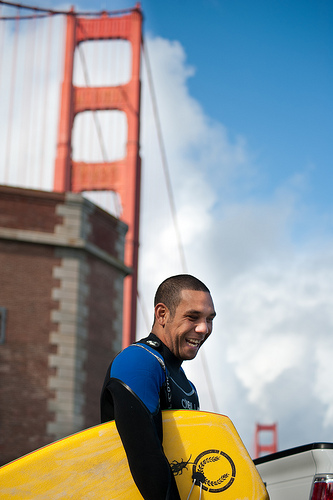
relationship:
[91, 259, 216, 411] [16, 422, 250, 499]
man carrying surfboard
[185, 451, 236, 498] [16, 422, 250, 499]
logo on surfboard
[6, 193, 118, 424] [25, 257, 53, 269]
wall made of brick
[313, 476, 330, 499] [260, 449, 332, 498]
tail light of truck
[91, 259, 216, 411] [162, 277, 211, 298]
man has hair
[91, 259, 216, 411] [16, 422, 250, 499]
man holding surfboard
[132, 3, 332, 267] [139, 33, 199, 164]
sky has cloud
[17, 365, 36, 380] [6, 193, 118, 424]
brick in wall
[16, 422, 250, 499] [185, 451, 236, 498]
surfboard has logo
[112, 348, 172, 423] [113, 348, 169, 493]
wetsuit has sleeve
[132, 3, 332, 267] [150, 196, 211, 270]
sky has cloud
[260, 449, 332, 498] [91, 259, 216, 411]
truck behind man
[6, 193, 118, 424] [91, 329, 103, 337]
wall made of brick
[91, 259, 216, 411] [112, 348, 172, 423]
man wearing wetsuit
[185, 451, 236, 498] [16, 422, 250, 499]
logo printed on surfboard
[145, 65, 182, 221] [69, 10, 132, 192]
cable attached to bridge support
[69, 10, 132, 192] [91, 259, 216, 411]
bridge support behind man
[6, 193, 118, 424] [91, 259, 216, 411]
wall behind man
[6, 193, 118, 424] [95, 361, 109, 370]
wall made of brick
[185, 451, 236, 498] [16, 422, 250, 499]
logo under surfboard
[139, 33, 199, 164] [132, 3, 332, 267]
cloud in sky